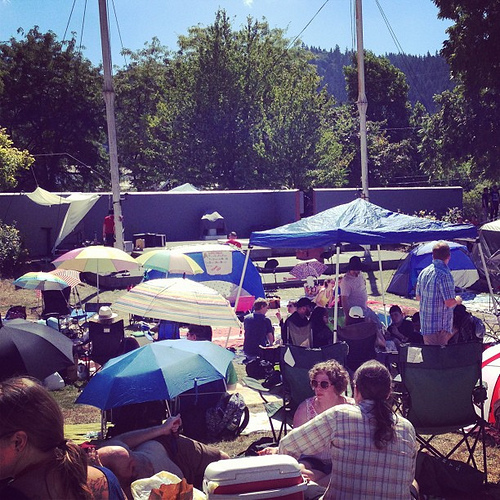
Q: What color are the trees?
A: Green.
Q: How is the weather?
A: Sunny.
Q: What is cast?
A: Shadow.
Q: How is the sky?
A: No clouds.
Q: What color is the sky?
A: Blue.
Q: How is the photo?
A: Clear.